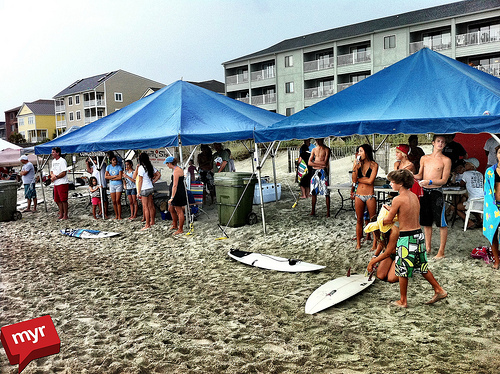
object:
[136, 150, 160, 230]
girl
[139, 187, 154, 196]
gray shorts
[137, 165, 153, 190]
white shirt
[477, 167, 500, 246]
towel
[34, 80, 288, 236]
tent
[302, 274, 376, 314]
surfboard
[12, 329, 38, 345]
letter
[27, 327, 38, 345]
letter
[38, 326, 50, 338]
letter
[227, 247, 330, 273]
white surfboard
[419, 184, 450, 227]
black trunks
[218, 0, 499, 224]
building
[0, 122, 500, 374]
beach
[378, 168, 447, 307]
boy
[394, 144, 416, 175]
woman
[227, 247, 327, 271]
surfboard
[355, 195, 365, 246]
leg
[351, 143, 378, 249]
woman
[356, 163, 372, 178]
bikini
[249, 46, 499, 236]
tent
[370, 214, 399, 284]
woman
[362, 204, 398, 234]
hat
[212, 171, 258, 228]
garbage_can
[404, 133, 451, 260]
man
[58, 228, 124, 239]
surfboard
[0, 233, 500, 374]
sand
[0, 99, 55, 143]
house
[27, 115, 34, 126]
window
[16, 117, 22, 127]
window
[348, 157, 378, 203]
suit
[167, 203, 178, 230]
leg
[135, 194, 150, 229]
leg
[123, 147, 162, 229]
woman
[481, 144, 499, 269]
person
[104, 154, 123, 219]
girl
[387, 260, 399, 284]
leg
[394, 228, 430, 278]
trunks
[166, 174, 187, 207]
bathing suit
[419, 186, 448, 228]
trunk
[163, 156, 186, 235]
woman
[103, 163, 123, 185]
shirt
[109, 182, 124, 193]
shorts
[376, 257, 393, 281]
leg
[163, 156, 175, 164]
cap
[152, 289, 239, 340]
sand